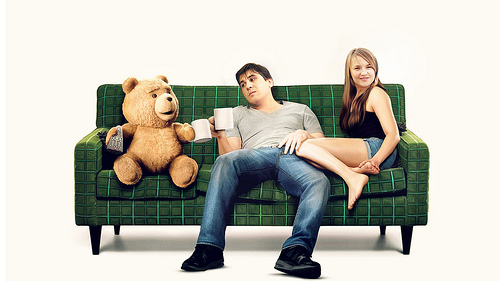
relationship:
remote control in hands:
[98, 128, 133, 155] [93, 120, 125, 135]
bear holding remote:
[104, 74, 196, 188] [95, 116, 128, 146]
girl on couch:
[294, 47, 400, 211] [79, 150, 418, 224]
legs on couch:
[80, 222, 136, 249] [71, 83, 431, 255]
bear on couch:
[107, 67, 191, 191] [60, 52, 434, 213]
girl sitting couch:
[312, 60, 393, 208] [77, 100, 442, 227]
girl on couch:
[294, 47, 400, 211] [80, 71, 450, 209]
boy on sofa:
[179, 61, 332, 279] [92, 81, 450, 253]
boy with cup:
[179, 61, 332, 279] [199, 96, 262, 138]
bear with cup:
[104, 74, 196, 188] [169, 111, 226, 152]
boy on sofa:
[208, 70, 325, 234] [89, 93, 437, 269]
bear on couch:
[104, 74, 196, 188] [48, 69, 452, 254]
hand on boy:
[281, 120, 309, 141] [179, 61, 332, 279]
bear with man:
[104, 74, 196, 188] [216, 63, 336, 214]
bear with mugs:
[104, 74, 196, 188] [175, 96, 258, 149]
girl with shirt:
[294, 47, 400, 211] [331, 87, 396, 138]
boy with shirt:
[179, 61, 332, 279] [215, 100, 324, 149]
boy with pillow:
[179, 61, 332, 279] [181, 160, 283, 198]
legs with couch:
[50, 215, 138, 255] [54, 88, 434, 240]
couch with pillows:
[67, 87, 385, 245] [100, 152, 428, 201]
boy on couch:
[179, 61, 332, 279] [67, 69, 453, 270]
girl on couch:
[294, 47, 400, 211] [67, 69, 453, 270]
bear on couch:
[104, 74, 196, 188] [80, 69, 448, 239]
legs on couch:
[83, 204, 439, 264] [88, 79, 453, 213]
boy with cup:
[179, 61, 332, 279] [197, 95, 269, 145]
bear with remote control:
[104, 74, 196, 188] [105, 124, 126, 154]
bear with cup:
[104, 74, 196, 188] [184, 104, 224, 144]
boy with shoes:
[179, 61, 332, 279] [178, 243, 322, 278]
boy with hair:
[179, 61, 332, 279] [234, 63, 276, 76]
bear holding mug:
[104, 74, 196, 188] [189, 118, 214, 146]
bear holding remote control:
[104, 74, 196, 188] [105, 124, 126, 154]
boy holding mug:
[179, 61, 332, 279] [212, 106, 236, 132]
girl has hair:
[294, 47, 400, 211] [342, 49, 382, 110]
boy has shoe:
[179, 61, 332, 279] [182, 246, 226, 275]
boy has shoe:
[179, 61, 332, 279] [274, 242, 324, 279]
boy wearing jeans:
[179, 61, 332, 279] [194, 142, 334, 256]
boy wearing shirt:
[179, 61, 332, 279] [212, 98, 321, 148]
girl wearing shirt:
[294, 47, 400, 211] [337, 90, 383, 139]